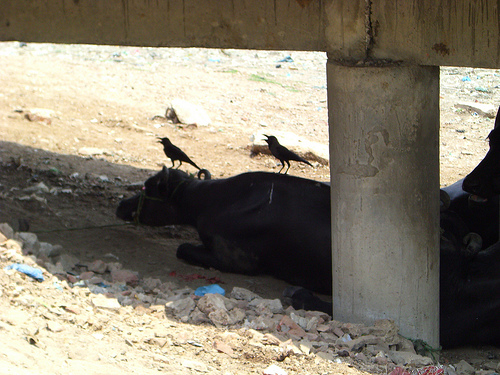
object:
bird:
[260, 134, 315, 176]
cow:
[114, 92, 453, 322]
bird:
[155, 136, 201, 171]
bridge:
[0, 0, 499, 363]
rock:
[164, 295, 196, 322]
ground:
[0, 41, 500, 374]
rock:
[5, 269, 20, 280]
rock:
[247, 296, 280, 316]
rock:
[27, 107, 57, 122]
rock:
[86, 259, 107, 274]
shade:
[0, 140, 498, 375]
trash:
[192, 284, 225, 298]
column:
[324, 62, 439, 367]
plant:
[405, 337, 447, 366]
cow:
[460, 107, 498, 200]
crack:
[361, 0, 376, 66]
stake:
[18, 216, 30, 234]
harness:
[136, 177, 204, 225]